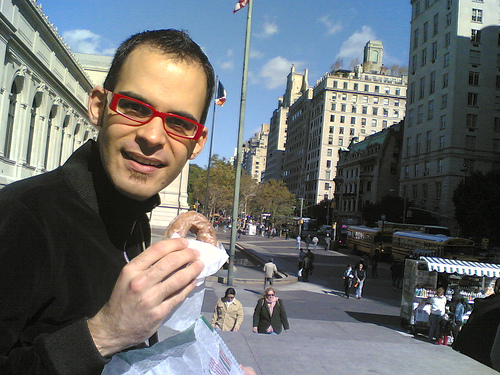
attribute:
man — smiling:
[1, 25, 211, 374]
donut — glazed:
[168, 206, 224, 244]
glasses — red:
[99, 89, 214, 143]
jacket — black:
[2, 141, 164, 374]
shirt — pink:
[266, 299, 276, 331]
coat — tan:
[209, 299, 244, 325]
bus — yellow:
[344, 226, 390, 258]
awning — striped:
[418, 254, 499, 280]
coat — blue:
[455, 301, 466, 322]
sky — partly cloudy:
[59, 5, 403, 66]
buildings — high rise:
[242, 41, 410, 185]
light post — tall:
[387, 187, 413, 226]